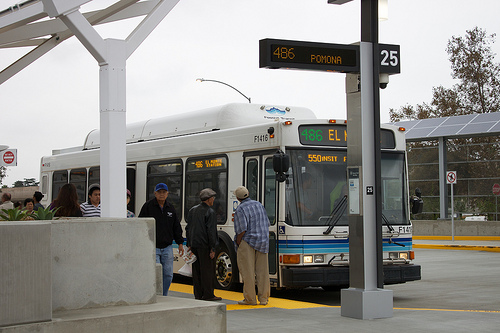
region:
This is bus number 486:
[288, 108, 335, 145]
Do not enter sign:
[2, 142, 26, 177]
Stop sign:
[485, 176, 498, 206]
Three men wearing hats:
[145, 172, 262, 211]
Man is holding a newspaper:
[174, 239, 207, 264]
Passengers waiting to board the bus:
[17, 179, 279, 279]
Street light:
[187, 67, 260, 102]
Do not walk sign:
[436, 160, 468, 192]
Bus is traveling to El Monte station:
[184, 149, 229, 172]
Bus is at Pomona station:
[305, 42, 355, 73]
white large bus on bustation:
[38, 97, 412, 274]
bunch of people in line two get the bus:
[2, 184, 274, 301]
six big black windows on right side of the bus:
[46, 149, 232, 230]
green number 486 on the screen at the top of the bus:
[300, 123, 326, 142]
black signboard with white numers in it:
[375, 42, 401, 70]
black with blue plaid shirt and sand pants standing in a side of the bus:
[235, 187, 272, 301]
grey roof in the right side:
[380, 109, 495, 139]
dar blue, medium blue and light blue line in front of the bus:
[278, 233, 413, 257]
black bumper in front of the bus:
[283, 264, 415, 284]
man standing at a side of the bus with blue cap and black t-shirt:
[138, 181, 180, 298]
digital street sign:
[242, 28, 375, 98]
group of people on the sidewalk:
[44, 149, 302, 316]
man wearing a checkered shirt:
[225, 184, 291, 264]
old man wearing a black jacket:
[179, 188, 233, 288]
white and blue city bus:
[29, 87, 460, 299]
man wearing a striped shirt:
[70, 170, 115, 239]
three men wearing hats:
[144, 169, 309, 302]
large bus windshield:
[276, 131, 446, 249]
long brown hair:
[39, 180, 79, 232]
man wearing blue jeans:
[125, 170, 210, 313]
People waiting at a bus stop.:
[10, 110, 286, 320]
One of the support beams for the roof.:
[50, 0, 162, 205]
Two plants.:
[0, 192, 80, 259]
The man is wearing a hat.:
[225, 180, 252, 211]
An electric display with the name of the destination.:
[240, 7, 410, 97]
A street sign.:
[435, 160, 465, 242]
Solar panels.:
[400, 100, 495, 140]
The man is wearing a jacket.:
[180, 200, 220, 260]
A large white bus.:
[30, 100, 405, 291]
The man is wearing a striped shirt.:
[75, 185, 106, 225]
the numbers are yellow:
[268, 41, 304, 68]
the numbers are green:
[297, 122, 327, 147]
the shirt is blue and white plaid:
[231, 202, 271, 234]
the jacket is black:
[183, 200, 220, 250]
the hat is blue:
[148, 178, 177, 198]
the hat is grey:
[193, 182, 222, 206]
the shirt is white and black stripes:
[79, 200, 108, 217]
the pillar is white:
[91, 62, 142, 214]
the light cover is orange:
[277, 245, 304, 272]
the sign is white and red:
[0, 144, 22, 171]